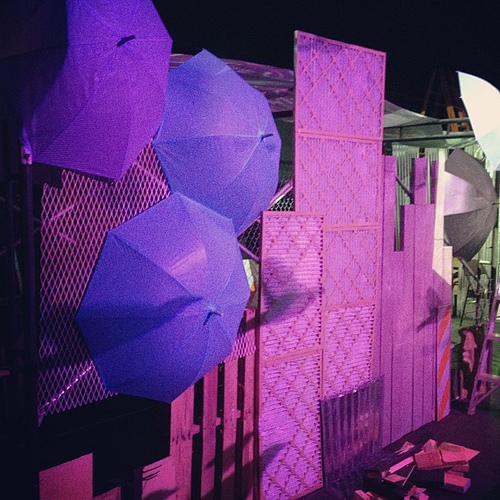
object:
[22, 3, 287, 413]
umbrellas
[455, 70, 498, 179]
umbrella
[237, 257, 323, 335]
shadow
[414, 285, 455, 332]
shadow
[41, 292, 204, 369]
shadow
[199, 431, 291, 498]
shadow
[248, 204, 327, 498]
pallet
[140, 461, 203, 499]
shadows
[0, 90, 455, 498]
wall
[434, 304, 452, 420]
construction sign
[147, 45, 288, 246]
umbrella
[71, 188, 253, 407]
umbrella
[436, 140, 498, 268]
umbrella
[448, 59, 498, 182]
umbrella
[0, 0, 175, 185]
umbrella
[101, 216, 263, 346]
umbrella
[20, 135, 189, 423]
grate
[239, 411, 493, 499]
ground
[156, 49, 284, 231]
umbrella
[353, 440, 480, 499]
blocks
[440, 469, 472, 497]
pile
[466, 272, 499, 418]
ladder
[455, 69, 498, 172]
grey umbrella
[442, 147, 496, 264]
grey umbrella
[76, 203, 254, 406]
top umbrella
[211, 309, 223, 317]
rod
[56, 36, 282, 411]
umbrellas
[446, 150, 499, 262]
umbrella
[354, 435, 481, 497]
blocks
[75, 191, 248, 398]
umbrella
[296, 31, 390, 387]
wall